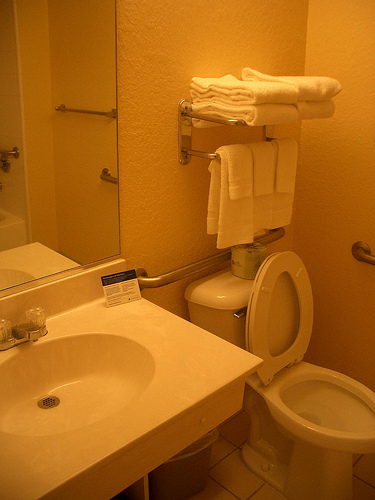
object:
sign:
[100, 268, 141, 308]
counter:
[0, 297, 263, 498]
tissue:
[231, 243, 269, 279]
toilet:
[0, 0, 373, 500]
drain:
[37, 396, 60, 410]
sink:
[0, 333, 155, 435]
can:
[151, 430, 220, 494]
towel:
[190, 67, 308, 128]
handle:
[135, 224, 284, 288]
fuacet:
[0, 307, 48, 351]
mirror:
[0, 0, 121, 292]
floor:
[190, 409, 375, 499]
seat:
[247, 250, 314, 388]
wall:
[0, 0, 375, 393]